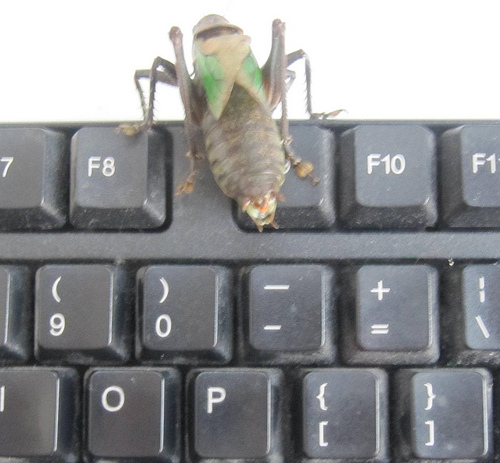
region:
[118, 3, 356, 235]
a creepy bug on top of a keyboard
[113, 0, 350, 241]
an insect on top of a computer keyboard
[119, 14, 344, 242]
an insect at the top edge of a keyboard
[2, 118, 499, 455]
the top three rows of a computer keyboard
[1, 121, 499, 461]
the top of a dirty black computer keyboard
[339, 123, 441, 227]
the F10 key on the keyboard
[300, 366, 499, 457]
the bracket keys on the keyboard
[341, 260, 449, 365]
the equal sign key on the keyboard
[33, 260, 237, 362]
the 9 and the 0 keys on the keyboard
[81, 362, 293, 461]
the O and P keys on the keyboard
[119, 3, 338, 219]
Grasshopper on a computer keyboard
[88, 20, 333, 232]
Grasshopper standing in between the F 8 in the F9 key on the computer keyboard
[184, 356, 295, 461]
The P keyboard key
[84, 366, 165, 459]
The letter O keyboard key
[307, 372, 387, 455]
Open bracket keyboard key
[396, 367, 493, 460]
Closed bracket keyboard key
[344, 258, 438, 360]
Plus and equal sign keyboard key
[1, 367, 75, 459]
The letter I keyboard key barely visible the photo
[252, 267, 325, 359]
The under score keyboard key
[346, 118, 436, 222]
The F10 keyboard key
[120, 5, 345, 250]
A grasshopper with green wings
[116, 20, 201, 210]
three Grasshopper legs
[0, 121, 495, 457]
A dusty black keyboard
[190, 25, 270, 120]
Green grasshopper wings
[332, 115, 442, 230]
F10 keyboard key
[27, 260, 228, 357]
Keyboard number keys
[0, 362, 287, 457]
Letter keys of a keyboard.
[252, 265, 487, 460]
Symbols on a keyboard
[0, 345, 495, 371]
Dust in between keys on a keyboard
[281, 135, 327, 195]
A grasshoppers foot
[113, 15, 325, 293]
grasshopper on keyboard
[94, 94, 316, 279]
bug on keyboard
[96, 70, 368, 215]
ugly insect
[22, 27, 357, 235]
unwanted guest on keyboard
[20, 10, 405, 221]
greenback bug on keyboard typewriter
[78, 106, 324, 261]
bug on f9 key on typewriter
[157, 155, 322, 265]
bug crawling on keyboard typewriter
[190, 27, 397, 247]
greenbacked insect on f9 keyboard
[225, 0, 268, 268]
ugly bug on typewriter keyboard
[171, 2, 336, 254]
grasshopper crawling on keyboard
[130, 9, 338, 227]
green and brown bug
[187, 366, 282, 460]
dirty black plastic P computer key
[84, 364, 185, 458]
dirty black plastic O computer key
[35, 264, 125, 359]
dirty black plastic 9 computer key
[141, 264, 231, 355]
dirty black plastic 0 computer key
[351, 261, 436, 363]
dirty black plastic + computer key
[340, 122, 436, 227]
dirty black plastic F10 computer key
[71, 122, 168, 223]
dirty black plastic F8 computer key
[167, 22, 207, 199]
brown long leg of bug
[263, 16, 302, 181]
brown long leg of bug